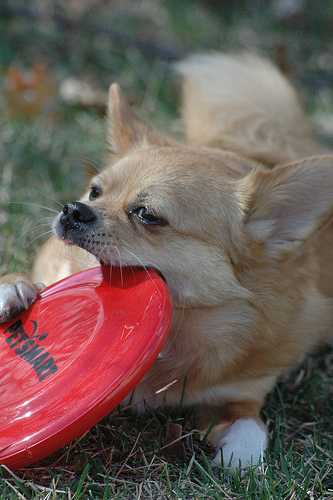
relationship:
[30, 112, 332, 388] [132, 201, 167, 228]
dog left eye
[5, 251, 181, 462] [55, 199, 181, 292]
frisbee in dogs mouth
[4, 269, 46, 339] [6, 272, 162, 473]
paw on frisbee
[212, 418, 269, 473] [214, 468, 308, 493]
paw on grass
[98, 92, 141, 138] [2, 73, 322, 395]
right ear of dog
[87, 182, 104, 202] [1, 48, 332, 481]
eye of dog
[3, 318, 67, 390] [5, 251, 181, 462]
word on a frisbee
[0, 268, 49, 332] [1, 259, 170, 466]
dog's paw on a frisbee